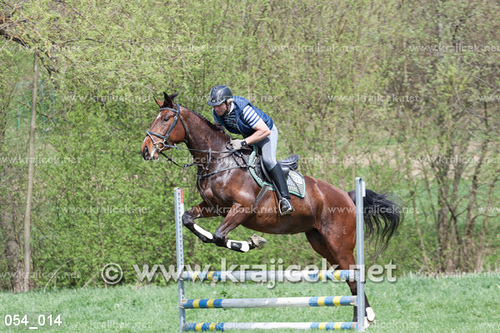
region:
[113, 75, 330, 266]
a man riding a horse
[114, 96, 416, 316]
a horse jump a rail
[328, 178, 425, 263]
a horses black tail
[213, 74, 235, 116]
a man wearing a helmet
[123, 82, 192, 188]
a horse wearing a bridle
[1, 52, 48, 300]
a tall skinny tree trunk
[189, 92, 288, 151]
a man wearing blue vest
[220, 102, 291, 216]
a man wearing black riding boots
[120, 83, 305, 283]
a horse with front legs off the ground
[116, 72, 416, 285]
a horse and rider jumping a obstical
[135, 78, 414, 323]
the horse is jumping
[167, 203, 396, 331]
the poles are metal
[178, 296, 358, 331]
the poles are blue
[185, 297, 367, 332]
the poles are yellow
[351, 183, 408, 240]
the horses tail is black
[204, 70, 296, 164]
the jockey is on the horse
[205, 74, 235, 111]
the jockey is wearing a helmet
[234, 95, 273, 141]
the jockey is wearing a blue vest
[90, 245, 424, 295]
the picture is watermarked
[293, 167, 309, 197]
the pad is under the saddle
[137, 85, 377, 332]
a man riding a red horse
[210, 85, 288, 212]
a man sitting atop a horse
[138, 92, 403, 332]
a horse jumping with a man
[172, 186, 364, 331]
hurdle being jumped by horse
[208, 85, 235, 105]
a man's riding helmet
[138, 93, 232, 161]
head of a red horse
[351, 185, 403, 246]
a red horses tail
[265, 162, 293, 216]
a man's riding boots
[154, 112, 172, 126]
a horse's left eye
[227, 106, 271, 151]
a man's left arm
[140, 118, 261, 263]
A horse is visible.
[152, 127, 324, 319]
A horse is visible.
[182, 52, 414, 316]
A horse is visible.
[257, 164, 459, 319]
A horse is visible.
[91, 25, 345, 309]
A horse is visible.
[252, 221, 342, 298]
A horse is visible.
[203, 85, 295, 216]
a man is leaning forward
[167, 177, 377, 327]
a metal fence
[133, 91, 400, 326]
a brown horse with a black tail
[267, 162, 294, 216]
tall black riding boots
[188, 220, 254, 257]
the horse is wearing white shin guards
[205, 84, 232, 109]
the rider has a black helmet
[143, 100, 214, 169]
the horse is wearing a black bridle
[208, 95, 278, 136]
the rider wears a blue vest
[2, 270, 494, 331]
the grass is lush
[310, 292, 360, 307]
blue and yellow stripes on the jump